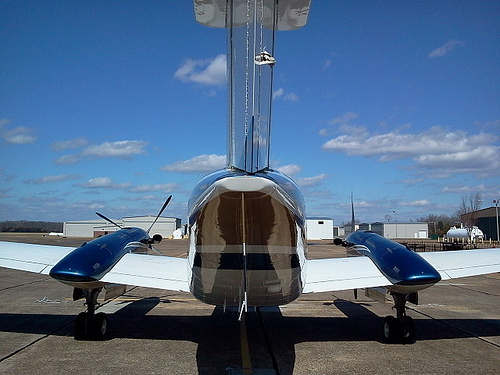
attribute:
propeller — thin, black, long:
[145, 195, 173, 236]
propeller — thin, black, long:
[95, 212, 124, 230]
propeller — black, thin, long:
[354, 287, 360, 299]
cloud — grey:
[21, 170, 80, 187]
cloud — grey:
[81, 189, 101, 196]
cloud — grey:
[2, 172, 17, 184]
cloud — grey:
[19, 195, 67, 204]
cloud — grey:
[46, 136, 90, 152]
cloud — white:
[167, 52, 230, 98]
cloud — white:
[156, 154, 229, 174]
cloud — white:
[78, 137, 148, 162]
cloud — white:
[321, 125, 500, 162]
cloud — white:
[413, 145, 500, 171]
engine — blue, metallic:
[343, 229, 443, 285]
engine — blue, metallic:
[49, 226, 152, 282]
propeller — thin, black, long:
[148, 244, 163, 254]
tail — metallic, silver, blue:
[193, 2, 312, 173]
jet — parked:
[0, 1, 499, 339]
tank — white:
[445, 225, 484, 240]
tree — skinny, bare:
[455, 192, 485, 242]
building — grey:
[62, 216, 181, 239]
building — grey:
[372, 221, 430, 242]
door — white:
[419, 229, 429, 239]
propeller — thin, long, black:
[304, 240, 345, 247]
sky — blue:
[1, 0, 499, 226]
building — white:
[305, 217, 334, 241]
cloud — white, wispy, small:
[426, 38, 465, 63]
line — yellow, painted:
[239, 294, 254, 374]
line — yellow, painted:
[62, 296, 203, 303]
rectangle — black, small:
[319, 221, 325, 225]